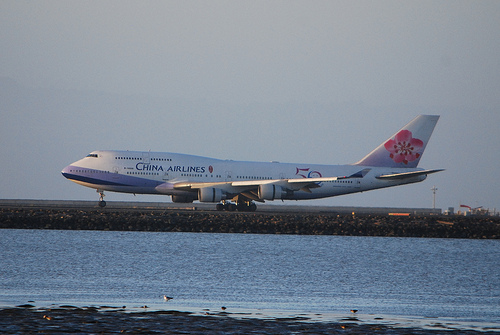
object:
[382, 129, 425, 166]
big flower on tail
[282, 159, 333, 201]
plane has a 50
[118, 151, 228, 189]
plane has writing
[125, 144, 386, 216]
plane has wing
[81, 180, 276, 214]
landing gear down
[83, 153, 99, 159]
cockpit of plane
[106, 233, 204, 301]
water is blue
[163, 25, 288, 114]
sky is grey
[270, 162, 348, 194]
wing covering number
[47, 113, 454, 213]
plane on landing are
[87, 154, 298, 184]
two levels of window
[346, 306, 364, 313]
birds along edge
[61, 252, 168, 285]
ripples across water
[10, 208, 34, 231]
rocks on side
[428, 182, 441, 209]
airport tower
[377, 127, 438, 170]
red logo on tail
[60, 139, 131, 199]
windows on the left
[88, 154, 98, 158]
cockpit window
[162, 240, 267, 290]
body of water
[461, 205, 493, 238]
water plant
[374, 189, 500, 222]
cities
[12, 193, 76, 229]
forestland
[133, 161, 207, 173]
china airline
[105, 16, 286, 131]
cloudless blue sky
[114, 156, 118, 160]
small windows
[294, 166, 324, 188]
number 50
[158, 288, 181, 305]
seagull in water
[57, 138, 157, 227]
airplane has blue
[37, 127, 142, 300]
in front of water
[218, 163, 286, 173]
main color is white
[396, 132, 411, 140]
airplanes color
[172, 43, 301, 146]
sky is cloudy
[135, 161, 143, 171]
capital letters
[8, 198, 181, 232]
landing area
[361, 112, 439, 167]
tail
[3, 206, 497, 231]
runway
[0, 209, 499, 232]
ground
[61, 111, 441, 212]
airplane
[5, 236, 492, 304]
water